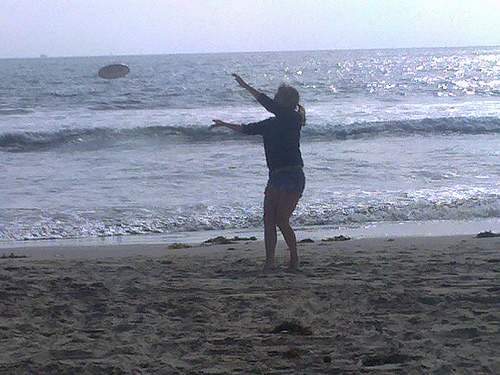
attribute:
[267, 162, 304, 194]
shorts — blue, jeans